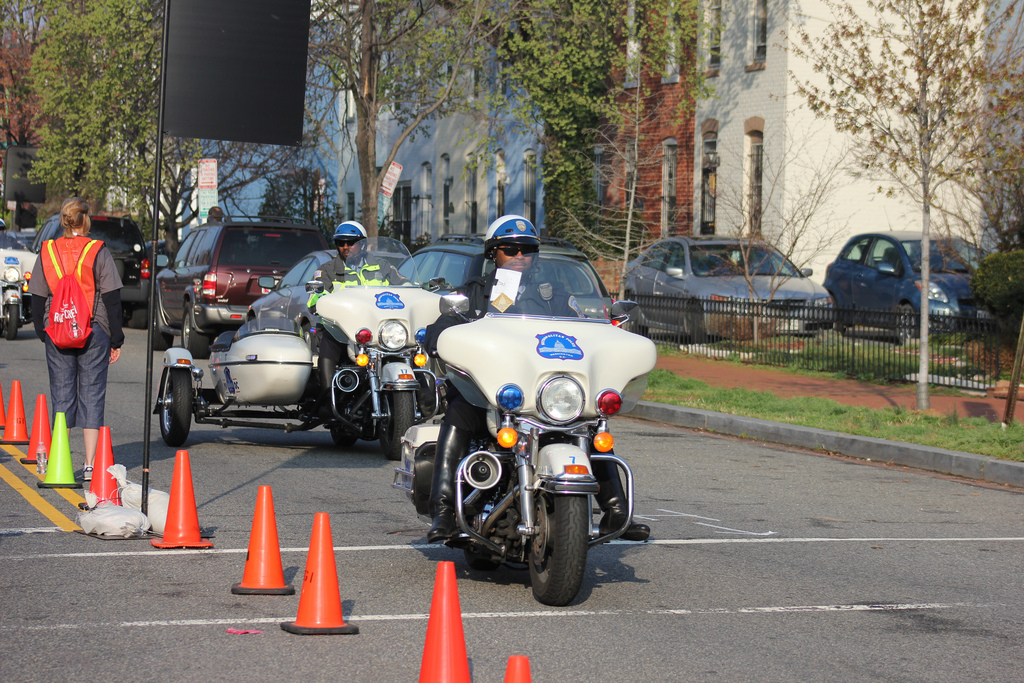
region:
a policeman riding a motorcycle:
[393, 214, 653, 607]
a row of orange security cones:
[2, 375, 531, 677]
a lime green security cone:
[38, 413, 77, 489]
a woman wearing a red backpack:
[45, 236, 84, 344]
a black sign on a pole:
[157, 0, 300, 141]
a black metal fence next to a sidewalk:
[602, 286, 996, 381]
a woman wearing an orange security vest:
[42, 235, 101, 324]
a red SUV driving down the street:
[149, 216, 334, 359]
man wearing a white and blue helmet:
[485, 214, 540, 271]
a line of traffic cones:
[2, 371, 568, 679]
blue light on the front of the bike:
[488, 371, 524, 411]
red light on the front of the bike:
[598, 379, 622, 422]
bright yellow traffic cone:
[36, 405, 84, 489]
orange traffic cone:
[149, 449, 233, 545]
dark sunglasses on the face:
[500, 226, 543, 255]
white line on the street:
[617, 510, 1023, 549]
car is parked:
[584, 200, 829, 350]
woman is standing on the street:
[23, 178, 163, 496]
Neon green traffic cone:
[27, 404, 79, 506]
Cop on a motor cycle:
[294, 214, 449, 448]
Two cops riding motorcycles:
[308, 211, 662, 601]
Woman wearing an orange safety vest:
[20, 193, 132, 453]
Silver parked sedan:
[614, 224, 840, 339]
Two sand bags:
[57, 448, 179, 547]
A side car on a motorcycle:
[147, 290, 439, 449]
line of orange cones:
[0, 384, 526, 679]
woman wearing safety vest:
[16, 188, 157, 473]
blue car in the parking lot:
[830, 209, 986, 336]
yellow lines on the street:
[7, 425, 109, 517]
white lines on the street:
[18, 516, 1020, 679]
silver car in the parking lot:
[632, 228, 826, 328]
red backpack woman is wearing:
[40, 270, 91, 341]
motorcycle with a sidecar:
[149, 272, 428, 449]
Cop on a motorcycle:
[396, 213, 656, 607]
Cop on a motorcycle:
[153, 206, 445, 457]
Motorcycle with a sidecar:
[157, 325, 329, 447]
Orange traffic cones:
[2, 373, 534, 680]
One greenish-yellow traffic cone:
[33, 405, 84, 491]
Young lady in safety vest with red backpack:
[38, 188, 119, 482]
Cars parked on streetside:
[21, 212, 623, 384]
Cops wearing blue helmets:
[324, 213, 537, 251]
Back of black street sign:
[150, 3, 307, 146]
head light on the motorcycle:
[534, 360, 595, 425]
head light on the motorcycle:
[379, 322, 415, 349]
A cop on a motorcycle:
[464, 214, 695, 607]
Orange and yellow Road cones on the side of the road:
[6, 388, 522, 528]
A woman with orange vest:
[9, 167, 121, 510]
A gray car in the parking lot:
[638, 198, 806, 430]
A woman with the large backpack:
[31, 253, 114, 372]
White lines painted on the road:
[601, 500, 897, 679]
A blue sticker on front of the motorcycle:
[496, 329, 608, 374]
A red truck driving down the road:
[35, 161, 364, 395]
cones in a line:
[153, 450, 445, 643]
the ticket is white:
[485, 270, 527, 332]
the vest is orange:
[51, 244, 106, 342]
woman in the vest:
[43, 198, 142, 455]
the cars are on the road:
[656, 204, 1017, 353]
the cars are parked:
[169, 231, 609, 339]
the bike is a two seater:
[191, 289, 441, 436]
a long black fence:
[614, 277, 1007, 389]